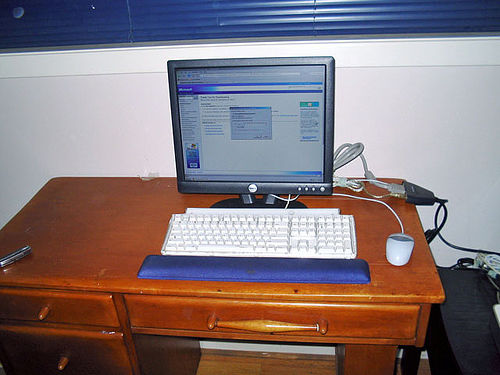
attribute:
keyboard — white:
[171, 218, 353, 251]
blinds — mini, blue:
[2, 1, 498, 43]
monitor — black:
[157, 52, 342, 218]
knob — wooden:
[35, 308, 50, 319]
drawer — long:
[127, 298, 446, 349]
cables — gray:
[332, 142, 404, 201]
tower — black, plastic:
[430, 257, 499, 372]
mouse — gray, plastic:
[381, 224, 442, 276]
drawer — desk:
[119, 288, 423, 350]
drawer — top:
[3, 288, 120, 332]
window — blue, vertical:
[88, 1, 474, 44]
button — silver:
[318, 185, 327, 191]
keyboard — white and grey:
[161, 208, 356, 265]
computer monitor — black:
[162, 55, 338, 209]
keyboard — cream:
[157, 205, 357, 261]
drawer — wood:
[120, 295, 422, 339]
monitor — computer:
[162, 54, 333, 195]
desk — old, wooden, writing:
[35, 146, 442, 339]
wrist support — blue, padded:
[144, 252, 371, 288]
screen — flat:
[175, 55, 342, 194]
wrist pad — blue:
[136, 255, 373, 288]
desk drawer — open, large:
[182, 303, 339, 355]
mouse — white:
[379, 211, 417, 276]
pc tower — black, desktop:
[437, 270, 499, 367]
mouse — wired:
[385, 234, 413, 266]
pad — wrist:
[151, 249, 299, 294]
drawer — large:
[124, 289, 438, 346]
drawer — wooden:
[116, 261, 484, 365]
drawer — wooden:
[22, 330, 124, 368]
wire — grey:
[334, 139, 403, 189]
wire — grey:
[334, 176, 402, 199]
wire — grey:
[271, 196, 411, 234]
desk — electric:
[2, 175, 448, 369]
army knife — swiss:
[0, 234, 35, 270]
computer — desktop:
[168, 68, 348, 243]